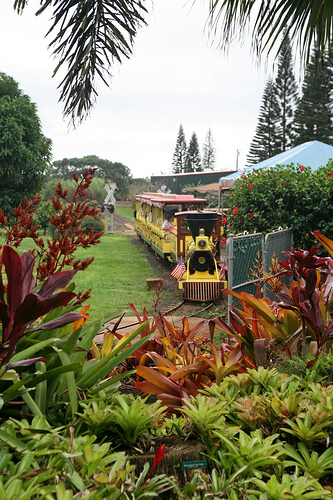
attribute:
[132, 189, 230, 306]
train — yellow, small, for tourists, red, black, little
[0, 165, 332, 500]
plants — around tree stump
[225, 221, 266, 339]
metal gate — tall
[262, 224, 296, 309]
metal gate — tall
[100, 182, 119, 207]
crossing sign — white, black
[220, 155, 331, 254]
tree top — large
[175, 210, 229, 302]
front of train — yellow, black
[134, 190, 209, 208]
roof — red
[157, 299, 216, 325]
part of track — brown metal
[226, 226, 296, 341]
chain link gate — metal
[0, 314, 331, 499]
green plants — little, lush green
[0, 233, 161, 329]
grass — green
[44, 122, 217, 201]
trees in the distanc — green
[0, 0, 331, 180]
sky — overcast, white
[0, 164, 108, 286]
plant — red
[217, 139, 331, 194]
awning — light blue, green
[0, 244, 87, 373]
plant — purple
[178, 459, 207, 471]
sign — green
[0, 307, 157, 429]
plant — green